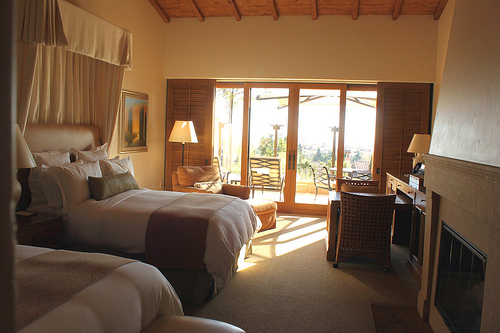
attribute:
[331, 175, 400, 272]
chair — brown, wooden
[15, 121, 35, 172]
lamp shade — white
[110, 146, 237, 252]
cover — brown, white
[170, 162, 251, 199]
chair — tan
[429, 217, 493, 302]
vent — black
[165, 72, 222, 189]
door — Slated, wooden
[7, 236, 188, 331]
cover — white, brown